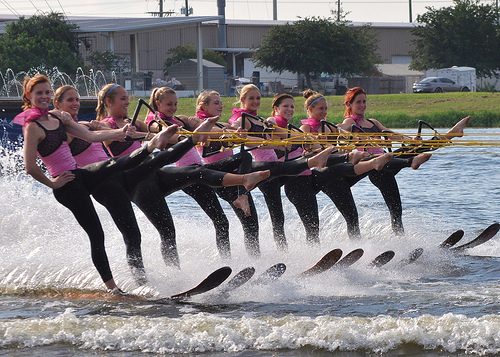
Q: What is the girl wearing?
A: Pink and black.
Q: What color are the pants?
A: Black.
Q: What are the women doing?
A: Water skiing.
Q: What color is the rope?
A: Yellow.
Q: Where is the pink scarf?
A: Around the neck.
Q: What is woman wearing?
A: Scarf.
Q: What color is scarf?
A: Pink.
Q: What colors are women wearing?
A: Pink and black.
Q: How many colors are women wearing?
A: Two.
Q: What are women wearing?
A: Pink and black.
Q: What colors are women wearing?
A: Pink and black.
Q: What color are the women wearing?
A: Pink and black.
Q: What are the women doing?
A: Water skiing.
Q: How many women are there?
A: 9.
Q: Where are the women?
A: Water.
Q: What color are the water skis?
A: Black.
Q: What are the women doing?
A: Water skiing.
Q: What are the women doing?
A: Performing.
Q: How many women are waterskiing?
A: 9.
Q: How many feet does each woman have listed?
A: 1.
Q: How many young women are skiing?
A: 9.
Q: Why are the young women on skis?
A: Performing ski stunts.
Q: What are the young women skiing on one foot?
A: Ski performance.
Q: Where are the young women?
A: Skiing on the water in a lake.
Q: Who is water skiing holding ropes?
A: Young women.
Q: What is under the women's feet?
A: Skis.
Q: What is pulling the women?
A: Boat.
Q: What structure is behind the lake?
A: A one story building.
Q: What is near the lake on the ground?
A: Water fountain.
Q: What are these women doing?
A: Waterskiing.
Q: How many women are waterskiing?
A: Nine.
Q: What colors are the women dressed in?
A: Pink and black.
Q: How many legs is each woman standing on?
A: One.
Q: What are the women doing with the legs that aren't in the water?
A: Kicking them forward.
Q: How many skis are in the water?
A: Nine.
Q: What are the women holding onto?
A: A rope.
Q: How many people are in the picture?
A: Nine.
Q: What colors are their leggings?
A: Black.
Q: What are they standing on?
A: Water skis.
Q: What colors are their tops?
A: Pink and black.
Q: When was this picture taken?
A: During the day.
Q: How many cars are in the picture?
A: One.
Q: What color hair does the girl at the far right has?
A: Red.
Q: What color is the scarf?
A: Pink.